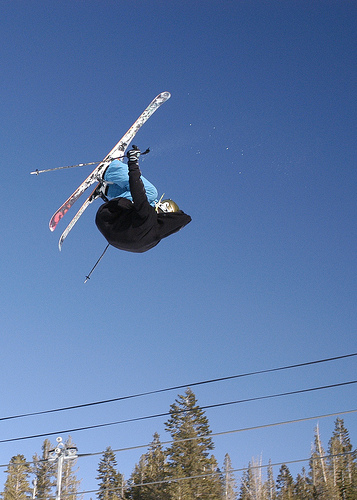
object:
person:
[89, 140, 191, 253]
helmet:
[156, 196, 180, 211]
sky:
[0, 0, 357, 500]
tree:
[139, 386, 227, 500]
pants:
[101, 155, 160, 207]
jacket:
[94, 158, 193, 255]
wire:
[0, 352, 357, 425]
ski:
[49, 92, 171, 237]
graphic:
[49, 190, 75, 230]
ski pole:
[28, 145, 153, 179]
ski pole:
[82, 238, 110, 286]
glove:
[123, 142, 144, 170]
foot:
[97, 153, 114, 187]